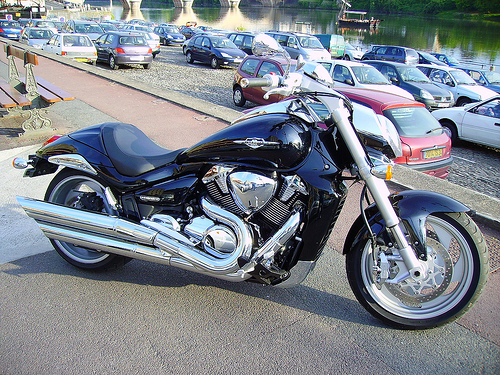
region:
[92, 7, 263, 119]
plenty cars were parked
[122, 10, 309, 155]
plenty cars were parked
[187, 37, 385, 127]
plenty cars were parked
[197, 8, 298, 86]
plenty cars were parked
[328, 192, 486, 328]
Front tire of the bike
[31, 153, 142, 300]
Back tire of the bike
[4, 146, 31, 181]
Back right turn signal on the bike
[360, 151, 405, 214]
front right turn signal on the bike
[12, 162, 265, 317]
right exhaust of the bike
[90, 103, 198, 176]
seat on the bike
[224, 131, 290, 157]
emblem on the right of the bike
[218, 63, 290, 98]
right handlebar of the bike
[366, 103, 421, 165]
front headlight on the bike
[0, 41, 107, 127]
bench behind the bike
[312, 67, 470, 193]
red car parked in the lot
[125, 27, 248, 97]
a gravel parking lot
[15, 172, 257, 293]
silver exhaust pipes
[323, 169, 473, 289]
black fender on the bike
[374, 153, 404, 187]
yellow headlight on the bike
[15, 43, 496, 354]
a large black motorcycle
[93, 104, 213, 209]
black seat to the bike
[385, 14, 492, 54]
a green body of water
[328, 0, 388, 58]
a boat in the water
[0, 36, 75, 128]
a bench on the ground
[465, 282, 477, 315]
edge of a wheel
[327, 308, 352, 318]
part of a shade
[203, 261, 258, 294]
part of a metal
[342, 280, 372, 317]
edge of a wheel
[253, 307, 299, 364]
part of a road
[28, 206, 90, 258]
part of a metal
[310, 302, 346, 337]
edge of a shade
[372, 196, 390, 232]
part of a metal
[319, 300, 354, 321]
part of a shade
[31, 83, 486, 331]
the black color bike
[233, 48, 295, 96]
the red color car parked in the parking area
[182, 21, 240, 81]
the blue color car parked in the parking area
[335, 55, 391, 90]
the white color car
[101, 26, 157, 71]
the violet car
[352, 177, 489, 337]
the black color tyre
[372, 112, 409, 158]
the white color light of the bike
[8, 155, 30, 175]
the yellow color signal light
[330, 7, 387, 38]
the boat in the river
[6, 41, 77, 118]
the wooden bench in the river side